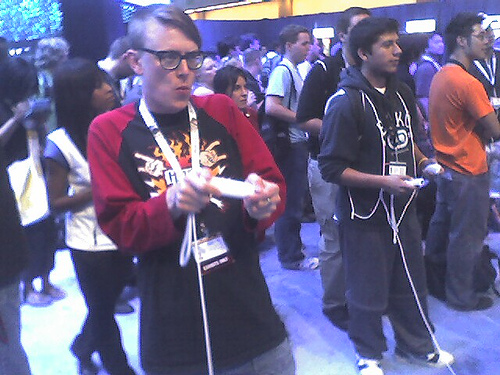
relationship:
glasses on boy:
[133, 48, 205, 69] [81, 1, 298, 374]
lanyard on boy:
[137, 102, 204, 169] [81, 1, 298, 374]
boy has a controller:
[81, 1, 298, 374] [207, 174, 256, 199]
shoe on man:
[357, 356, 385, 375] [318, 15, 446, 371]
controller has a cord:
[207, 174, 256, 199] [191, 216, 215, 374]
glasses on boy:
[133, 48, 205, 69] [86, 4, 285, 375]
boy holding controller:
[86, 4, 285, 375] [207, 174, 256, 199]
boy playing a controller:
[86, 4, 285, 375] [209, 177, 255, 198]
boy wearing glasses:
[86, 4, 285, 375] [133, 48, 205, 69]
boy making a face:
[86, 4, 285, 375] [160, 64, 195, 108]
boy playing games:
[86, 4, 285, 375] [196, 167, 424, 201]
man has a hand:
[318, 15, 446, 371] [382, 172, 419, 198]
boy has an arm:
[86, 4, 285, 375] [218, 103, 291, 222]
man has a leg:
[318, 15, 446, 371] [336, 208, 389, 365]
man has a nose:
[318, 15, 446, 371] [394, 46, 402, 56]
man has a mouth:
[318, 15, 446, 371] [386, 56, 401, 64]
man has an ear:
[318, 15, 446, 371] [353, 44, 370, 60]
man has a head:
[318, 15, 446, 371] [348, 19, 402, 78]